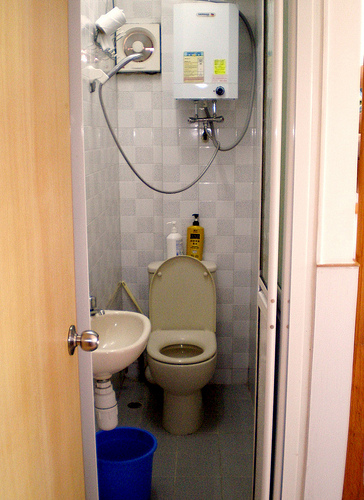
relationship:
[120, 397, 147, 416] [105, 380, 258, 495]
drain on floor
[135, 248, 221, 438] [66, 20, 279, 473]
toilet in bathroom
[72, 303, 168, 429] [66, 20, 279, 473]
sink in bathroom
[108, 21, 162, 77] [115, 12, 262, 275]
fan on wall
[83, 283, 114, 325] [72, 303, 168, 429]
faucet on sink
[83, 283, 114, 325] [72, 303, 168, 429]
faucet of sink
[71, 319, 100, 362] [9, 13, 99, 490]
knob on door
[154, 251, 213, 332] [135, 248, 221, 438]
lid on toilet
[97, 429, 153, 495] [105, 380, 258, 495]
bucket on floor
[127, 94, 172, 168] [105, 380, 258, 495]
tile on floor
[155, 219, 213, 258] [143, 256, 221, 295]
products on tank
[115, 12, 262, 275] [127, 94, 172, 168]
wall has tile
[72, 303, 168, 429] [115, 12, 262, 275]
sink on wall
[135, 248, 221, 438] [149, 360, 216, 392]
toilet has bowl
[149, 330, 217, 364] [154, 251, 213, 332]
seat and lid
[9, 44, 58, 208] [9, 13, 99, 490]
wood on door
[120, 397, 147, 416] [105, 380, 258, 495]
drain on ground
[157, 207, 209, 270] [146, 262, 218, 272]
bottles on back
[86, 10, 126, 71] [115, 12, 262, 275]
shower on wall